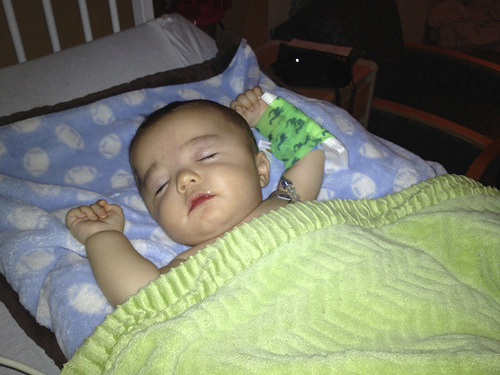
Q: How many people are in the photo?
A: One.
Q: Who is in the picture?
A: A baby.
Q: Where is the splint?
A: On the baby's left arm.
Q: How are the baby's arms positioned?
A: Raised next to the baby's head.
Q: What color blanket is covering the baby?
A: Light green.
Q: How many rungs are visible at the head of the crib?
A: Four.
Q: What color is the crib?
A: White.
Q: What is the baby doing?
A: Sleeping.